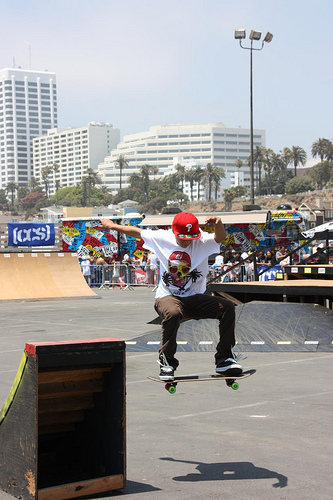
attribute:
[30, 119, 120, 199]
building — white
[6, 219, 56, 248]
sign — blue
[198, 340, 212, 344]
dash — white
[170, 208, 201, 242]
cap — baseball, red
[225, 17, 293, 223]
light pole — tall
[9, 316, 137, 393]
ramp — skateboard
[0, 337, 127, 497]
ramp — skateboard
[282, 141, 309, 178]
tree — tall, green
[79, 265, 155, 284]
fence — gray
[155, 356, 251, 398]
skateboard — long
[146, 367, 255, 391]
skateboard — white and black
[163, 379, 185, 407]
wheel — green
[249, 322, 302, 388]
dash — white